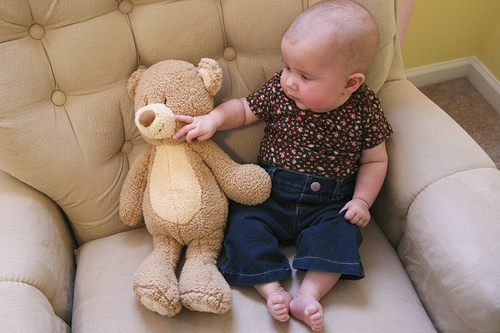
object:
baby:
[171, 1, 394, 333]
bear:
[119, 57, 271, 317]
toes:
[304, 306, 318, 317]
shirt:
[244, 70, 394, 178]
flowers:
[296, 126, 303, 133]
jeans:
[217, 156, 365, 289]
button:
[310, 182, 321, 192]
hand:
[174, 114, 223, 142]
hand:
[339, 199, 371, 228]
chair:
[0, 0, 500, 333]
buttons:
[50, 91, 67, 106]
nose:
[138, 109, 156, 127]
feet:
[261, 291, 294, 322]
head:
[126, 58, 223, 146]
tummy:
[148, 145, 202, 225]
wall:
[400, 0, 500, 88]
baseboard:
[407, 56, 499, 111]